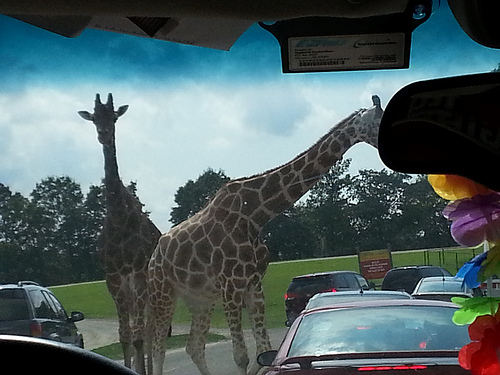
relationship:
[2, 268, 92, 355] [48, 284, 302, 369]
minivan on road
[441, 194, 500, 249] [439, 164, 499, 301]
purple flower on lei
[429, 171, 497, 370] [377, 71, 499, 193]
colorful lei hanging from mirror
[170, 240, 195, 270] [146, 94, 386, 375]
spot on animal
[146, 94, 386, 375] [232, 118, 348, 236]
animal with neck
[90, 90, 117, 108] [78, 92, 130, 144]
horns on head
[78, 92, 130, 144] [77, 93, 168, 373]
head on giraffe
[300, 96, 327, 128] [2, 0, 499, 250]
clouds in sky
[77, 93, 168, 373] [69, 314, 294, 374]
giraffe on road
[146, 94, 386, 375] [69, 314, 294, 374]
animal on road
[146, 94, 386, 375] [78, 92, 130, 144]
animal leaning head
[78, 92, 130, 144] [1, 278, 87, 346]
head over car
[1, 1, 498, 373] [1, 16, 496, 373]
car has windshield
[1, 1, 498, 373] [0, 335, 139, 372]
car has wheel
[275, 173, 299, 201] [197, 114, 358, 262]
spot on neck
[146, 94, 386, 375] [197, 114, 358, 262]
animal has neck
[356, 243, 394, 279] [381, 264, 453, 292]
sign ahead car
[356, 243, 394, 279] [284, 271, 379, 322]
sign ahead car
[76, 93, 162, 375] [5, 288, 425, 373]
giraffe are on road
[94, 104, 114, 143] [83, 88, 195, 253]
head of giraffe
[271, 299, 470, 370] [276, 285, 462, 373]
back of car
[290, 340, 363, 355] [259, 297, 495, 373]
light on car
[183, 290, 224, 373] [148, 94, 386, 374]
leg of animal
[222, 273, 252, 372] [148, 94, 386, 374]
leg of animal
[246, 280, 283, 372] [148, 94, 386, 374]
leg of animal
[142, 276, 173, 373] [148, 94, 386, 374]
leg of animal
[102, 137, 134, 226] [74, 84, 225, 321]
neck of giraffe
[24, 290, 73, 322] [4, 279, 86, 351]
windows on car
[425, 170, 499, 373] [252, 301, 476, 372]
stuff in car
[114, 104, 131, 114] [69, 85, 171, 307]
ear of giraffe